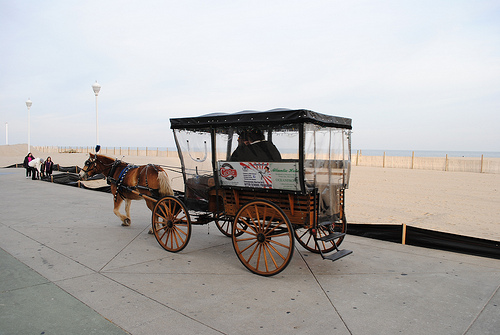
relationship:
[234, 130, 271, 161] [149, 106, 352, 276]
person inside carriage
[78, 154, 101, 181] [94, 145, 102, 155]
head has a taddel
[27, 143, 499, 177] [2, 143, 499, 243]
fence beside beach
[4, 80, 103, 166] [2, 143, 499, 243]
lights are beside beach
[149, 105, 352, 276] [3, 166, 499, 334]
carriage on pavement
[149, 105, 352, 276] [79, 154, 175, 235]
carriage being pulled by a horse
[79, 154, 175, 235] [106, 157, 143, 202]
horse has a harness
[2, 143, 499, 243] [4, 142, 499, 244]
beach covered by sand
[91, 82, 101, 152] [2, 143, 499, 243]
streetlight standing on beach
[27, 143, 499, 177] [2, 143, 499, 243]
fence running along beach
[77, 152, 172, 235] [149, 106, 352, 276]
horse front carriage